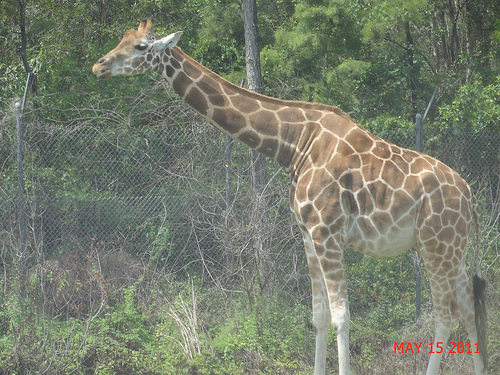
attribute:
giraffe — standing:
[96, 26, 488, 370]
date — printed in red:
[394, 336, 478, 358]